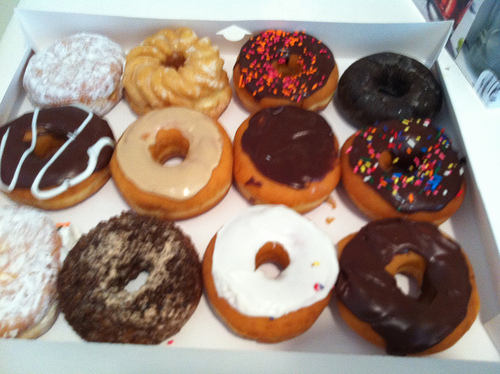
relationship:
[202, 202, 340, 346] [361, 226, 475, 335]
donut with frosting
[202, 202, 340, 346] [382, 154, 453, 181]
donut with sprinkles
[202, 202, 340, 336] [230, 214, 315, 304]
donut with frosting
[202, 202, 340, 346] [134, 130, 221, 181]
donut with frosting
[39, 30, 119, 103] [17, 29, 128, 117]
powder covering donut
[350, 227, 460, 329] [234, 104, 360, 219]
frosted covering donut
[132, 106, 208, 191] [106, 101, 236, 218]
frosting on donut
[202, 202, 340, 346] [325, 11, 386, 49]
donut inside box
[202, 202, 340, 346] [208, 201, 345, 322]
donut has frosted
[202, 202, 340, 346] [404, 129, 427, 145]
donut has sprinkles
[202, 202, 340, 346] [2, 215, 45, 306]
donut covered in sugar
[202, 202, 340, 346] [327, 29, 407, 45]
donut in box